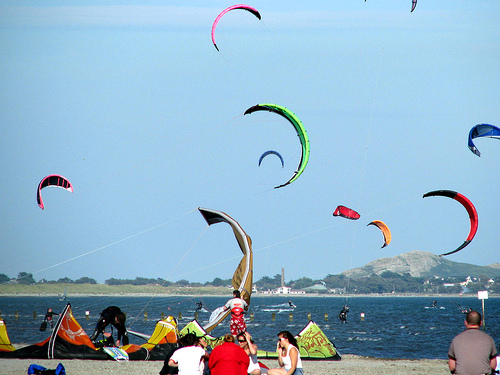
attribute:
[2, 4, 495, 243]
sky — clear, blue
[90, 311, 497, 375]
people — sitting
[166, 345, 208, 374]
shirt — white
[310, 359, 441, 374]
sand — gray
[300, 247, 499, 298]
mountain — large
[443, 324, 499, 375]
gray shirt — brown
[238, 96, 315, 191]
kite — green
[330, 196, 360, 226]
sail — red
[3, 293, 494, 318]
body of water — blue, large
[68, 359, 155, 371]
beach — sandy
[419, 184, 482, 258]
kite — red, black, orange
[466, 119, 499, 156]
kite — blue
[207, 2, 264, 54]
kite — pink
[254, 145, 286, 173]
kite — blue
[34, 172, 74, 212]
kite — blue, pink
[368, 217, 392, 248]
kite — orange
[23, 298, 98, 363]
kite — orange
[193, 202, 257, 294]
kite — brown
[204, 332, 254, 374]
shirt — red